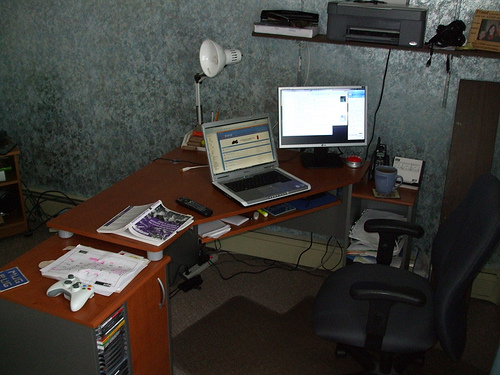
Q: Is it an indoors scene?
A: Yes, it is indoors.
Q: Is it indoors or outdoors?
A: It is indoors.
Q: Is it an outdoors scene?
A: No, it is indoors.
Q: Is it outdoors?
A: No, it is indoors.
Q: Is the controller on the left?
A: Yes, the controller is on the left of the image.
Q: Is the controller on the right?
A: No, the controller is on the left of the image.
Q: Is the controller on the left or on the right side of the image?
A: The controller is on the left of the image.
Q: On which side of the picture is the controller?
A: The controller is on the left of the image.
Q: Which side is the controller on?
A: The controller is on the left of the image.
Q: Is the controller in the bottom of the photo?
A: Yes, the controller is in the bottom of the image.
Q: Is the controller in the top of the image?
A: No, the controller is in the bottom of the image.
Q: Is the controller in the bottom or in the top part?
A: The controller is in the bottom of the image.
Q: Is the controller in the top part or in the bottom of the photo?
A: The controller is in the bottom of the image.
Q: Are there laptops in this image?
A: Yes, there is a laptop.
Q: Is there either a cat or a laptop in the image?
A: Yes, there is a laptop.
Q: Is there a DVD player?
A: No, there are no DVD players.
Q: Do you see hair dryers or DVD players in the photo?
A: No, there are no DVD players or hair dryers.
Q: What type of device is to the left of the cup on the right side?
A: The device is a laptop.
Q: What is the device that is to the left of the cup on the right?
A: The device is a laptop.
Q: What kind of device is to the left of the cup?
A: The device is a laptop.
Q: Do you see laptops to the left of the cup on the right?
A: Yes, there is a laptop to the left of the cup.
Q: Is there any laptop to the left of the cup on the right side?
A: Yes, there is a laptop to the left of the cup.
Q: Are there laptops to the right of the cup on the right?
A: No, the laptop is to the left of the cup.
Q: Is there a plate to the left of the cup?
A: No, there is a laptop to the left of the cup.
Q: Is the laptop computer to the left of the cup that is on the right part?
A: Yes, the laptop computer is to the left of the cup.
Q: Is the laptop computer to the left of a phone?
A: No, the laptop computer is to the left of the cup.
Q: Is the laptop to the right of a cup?
A: No, the laptop is to the left of a cup.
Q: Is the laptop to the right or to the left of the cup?
A: The laptop is to the left of the cup.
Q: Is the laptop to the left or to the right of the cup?
A: The laptop is to the left of the cup.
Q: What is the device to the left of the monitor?
A: The device is a laptop.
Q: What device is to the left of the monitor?
A: The device is a laptop.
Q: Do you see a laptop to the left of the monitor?
A: Yes, there is a laptop to the left of the monitor.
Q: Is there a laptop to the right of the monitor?
A: No, the laptop is to the left of the monitor.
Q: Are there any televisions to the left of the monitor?
A: No, there is a laptop to the left of the monitor.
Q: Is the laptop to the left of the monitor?
A: Yes, the laptop is to the left of the monitor.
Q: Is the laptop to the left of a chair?
A: No, the laptop is to the left of the monitor.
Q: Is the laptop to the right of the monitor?
A: No, the laptop is to the left of the monitor.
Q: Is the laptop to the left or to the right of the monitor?
A: The laptop is to the left of the monitor.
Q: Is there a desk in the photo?
A: Yes, there is a desk.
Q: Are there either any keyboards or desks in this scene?
A: Yes, there is a desk.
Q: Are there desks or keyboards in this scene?
A: Yes, there is a desk.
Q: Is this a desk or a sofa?
A: This is a desk.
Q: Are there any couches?
A: No, there are no couches.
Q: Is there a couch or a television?
A: No, there are no couches or televisions.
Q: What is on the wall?
A: The shelf is on the wall.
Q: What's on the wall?
A: The shelf is on the wall.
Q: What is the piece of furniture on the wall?
A: The piece of furniture is a shelf.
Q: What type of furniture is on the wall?
A: The piece of furniture is a shelf.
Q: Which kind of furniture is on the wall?
A: The piece of furniture is a shelf.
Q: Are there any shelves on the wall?
A: Yes, there is a shelf on the wall.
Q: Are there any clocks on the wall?
A: No, there is a shelf on the wall.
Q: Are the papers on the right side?
A: Yes, the papers are on the right of the image.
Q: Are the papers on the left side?
A: No, the papers are on the right of the image.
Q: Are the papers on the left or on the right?
A: The papers are on the right of the image.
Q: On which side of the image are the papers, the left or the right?
A: The papers are on the right of the image.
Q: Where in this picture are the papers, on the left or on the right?
A: The papers are on the right of the image.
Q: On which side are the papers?
A: The papers are on the right of the image.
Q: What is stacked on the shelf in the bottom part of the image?
A: The papers are stacked on the shelf.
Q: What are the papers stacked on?
A: The papers are stacked on the shelf.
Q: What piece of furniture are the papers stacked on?
A: The papers are stacked on the shelf.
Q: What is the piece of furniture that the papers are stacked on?
A: The piece of furniture is a shelf.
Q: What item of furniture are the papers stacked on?
A: The papers are stacked on the shelf.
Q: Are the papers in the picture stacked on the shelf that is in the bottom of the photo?
A: Yes, the papers are stacked on the shelf.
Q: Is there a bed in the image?
A: No, there are no beds.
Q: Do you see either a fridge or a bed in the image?
A: No, there are no beds or refrigerators.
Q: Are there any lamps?
A: Yes, there is a lamp.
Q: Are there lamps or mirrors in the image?
A: Yes, there is a lamp.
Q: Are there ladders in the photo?
A: No, there are no ladders.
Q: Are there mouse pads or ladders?
A: No, there are no ladders or mouse pads.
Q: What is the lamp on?
A: The lamp is on the desk.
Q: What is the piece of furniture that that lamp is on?
A: The piece of furniture is a desk.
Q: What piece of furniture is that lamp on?
A: The lamp is on the desk.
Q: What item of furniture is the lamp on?
A: The lamp is on the desk.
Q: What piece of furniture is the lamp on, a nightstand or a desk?
A: The lamp is on a desk.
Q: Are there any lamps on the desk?
A: Yes, there is a lamp on the desk.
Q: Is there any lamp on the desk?
A: Yes, there is a lamp on the desk.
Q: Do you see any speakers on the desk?
A: No, there is a lamp on the desk.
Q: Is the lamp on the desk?
A: Yes, the lamp is on the desk.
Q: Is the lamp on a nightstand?
A: No, the lamp is on the desk.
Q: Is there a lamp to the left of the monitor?
A: Yes, there is a lamp to the left of the monitor.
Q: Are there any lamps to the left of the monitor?
A: Yes, there is a lamp to the left of the monitor.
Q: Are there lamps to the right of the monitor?
A: No, the lamp is to the left of the monitor.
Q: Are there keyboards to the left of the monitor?
A: No, there is a lamp to the left of the monitor.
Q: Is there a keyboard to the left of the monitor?
A: No, there is a lamp to the left of the monitor.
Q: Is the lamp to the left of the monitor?
A: Yes, the lamp is to the left of the monitor.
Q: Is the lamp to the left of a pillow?
A: No, the lamp is to the left of the monitor.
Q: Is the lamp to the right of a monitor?
A: No, the lamp is to the left of a monitor.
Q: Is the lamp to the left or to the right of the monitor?
A: The lamp is to the left of the monitor.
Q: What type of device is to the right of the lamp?
A: The device is a monitor.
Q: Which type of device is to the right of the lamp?
A: The device is a monitor.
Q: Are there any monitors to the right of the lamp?
A: Yes, there is a monitor to the right of the lamp.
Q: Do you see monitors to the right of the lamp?
A: Yes, there is a monitor to the right of the lamp.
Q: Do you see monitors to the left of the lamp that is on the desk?
A: No, the monitor is to the right of the lamp.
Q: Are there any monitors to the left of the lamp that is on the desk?
A: No, the monitor is to the right of the lamp.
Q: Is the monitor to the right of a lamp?
A: Yes, the monitor is to the right of a lamp.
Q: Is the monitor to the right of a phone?
A: No, the monitor is to the right of a lamp.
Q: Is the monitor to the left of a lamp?
A: No, the monitor is to the right of a lamp.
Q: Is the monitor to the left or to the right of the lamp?
A: The monitor is to the right of the lamp.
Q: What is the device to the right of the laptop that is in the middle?
A: The device is a monitor.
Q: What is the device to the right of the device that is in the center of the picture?
A: The device is a monitor.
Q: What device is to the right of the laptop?
A: The device is a monitor.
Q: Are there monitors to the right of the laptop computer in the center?
A: Yes, there is a monitor to the right of the laptop.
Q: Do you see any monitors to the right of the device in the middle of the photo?
A: Yes, there is a monitor to the right of the laptop.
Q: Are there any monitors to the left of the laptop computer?
A: No, the monitor is to the right of the laptop computer.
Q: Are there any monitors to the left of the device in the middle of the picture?
A: No, the monitor is to the right of the laptop computer.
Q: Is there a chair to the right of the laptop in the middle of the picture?
A: No, there is a monitor to the right of the laptop.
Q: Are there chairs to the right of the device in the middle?
A: No, there is a monitor to the right of the laptop.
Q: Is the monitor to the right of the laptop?
A: Yes, the monitor is to the right of the laptop.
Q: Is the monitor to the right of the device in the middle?
A: Yes, the monitor is to the right of the laptop.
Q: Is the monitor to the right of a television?
A: No, the monitor is to the right of the laptop.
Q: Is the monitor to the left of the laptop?
A: No, the monitor is to the right of the laptop.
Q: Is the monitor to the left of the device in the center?
A: No, the monitor is to the right of the laptop.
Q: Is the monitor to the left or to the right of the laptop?
A: The monitor is to the right of the laptop.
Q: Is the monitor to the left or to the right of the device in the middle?
A: The monitor is to the right of the laptop.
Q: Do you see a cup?
A: Yes, there is a cup.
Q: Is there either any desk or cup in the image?
A: Yes, there is a cup.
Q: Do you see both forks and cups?
A: No, there is a cup but no forks.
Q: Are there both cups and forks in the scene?
A: No, there is a cup but no forks.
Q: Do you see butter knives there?
A: No, there are no butter knives.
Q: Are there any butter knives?
A: No, there are no butter knives.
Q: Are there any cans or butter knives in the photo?
A: No, there are no butter knives or cans.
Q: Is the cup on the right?
A: Yes, the cup is on the right of the image.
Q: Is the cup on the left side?
A: No, the cup is on the right of the image.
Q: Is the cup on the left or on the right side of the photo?
A: The cup is on the right of the image.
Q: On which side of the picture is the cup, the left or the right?
A: The cup is on the right of the image.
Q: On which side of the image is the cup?
A: The cup is on the right of the image.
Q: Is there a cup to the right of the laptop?
A: Yes, there is a cup to the right of the laptop.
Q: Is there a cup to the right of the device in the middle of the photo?
A: Yes, there is a cup to the right of the laptop.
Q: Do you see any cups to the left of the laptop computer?
A: No, the cup is to the right of the laptop computer.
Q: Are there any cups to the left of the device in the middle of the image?
A: No, the cup is to the right of the laptop computer.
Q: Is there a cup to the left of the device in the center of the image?
A: No, the cup is to the right of the laptop computer.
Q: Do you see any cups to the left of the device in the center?
A: No, the cup is to the right of the laptop computer.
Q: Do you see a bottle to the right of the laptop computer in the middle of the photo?
A: No, there is a cup to the right of the laptop.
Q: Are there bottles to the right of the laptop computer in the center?
A: No, there is a cup to the right of the laptop.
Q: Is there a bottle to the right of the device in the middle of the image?
A: No, there is a cup to the right of the laptop.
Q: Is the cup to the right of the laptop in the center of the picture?
A: Yes, the cup is to the right of the laptop.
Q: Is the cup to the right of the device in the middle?
A: Yes, the cup is to the right of the laptop.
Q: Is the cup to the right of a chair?
A: No, the cup is to the right of the laptop.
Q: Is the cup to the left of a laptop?
A: No, the cup is to the right of a laptop.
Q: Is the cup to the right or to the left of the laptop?
A: The cup is to the right of the laptop.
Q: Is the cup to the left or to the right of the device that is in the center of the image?
A: The cup is to the right of the laptop.